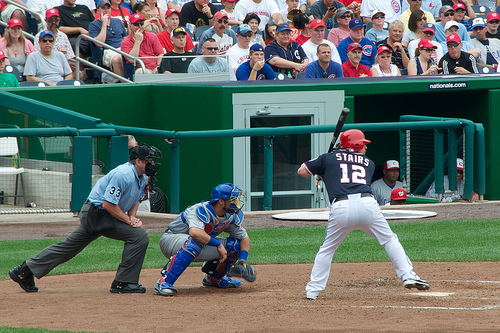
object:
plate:
[405, 291, 454, 296]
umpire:
[8, 143, 164, 294]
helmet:
[339, 129, 370, 153]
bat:
[314, 107, 351, 188]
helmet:
[208, 182, 243, 205]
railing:
[0, 91, 485, 217]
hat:
[128, 13, 146, 24]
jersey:
[302, 150, 376, 205]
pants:
[305, 191, 422, 297]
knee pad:
[160, 234, 204, 286]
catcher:
[154, 182, 257, 296]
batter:
[296, 128, 430, 300]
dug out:
[353, 88, 491, 206]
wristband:
[205, 235, 222, 249]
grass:
[0, 220, 499, 282]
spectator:
[304, 43, 345, 79]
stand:
[0, 0, 499, 90]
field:
[1, 200, 499, 333]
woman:
[406, 38, 443, 75]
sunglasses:
[418, 48, 436, 52]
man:
[437, 33, 480, 74]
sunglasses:
[446, 42, 461, 47]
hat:
[417, 38, 437, 49]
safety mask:
[144, 145, 163, 176]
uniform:
[153, 181, 257, 296]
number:
[339, 163, 367, 185]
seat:
[55, 79, 88, 86]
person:
[370, 159, 408, 205]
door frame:
[232, 89, 345, 212]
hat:
[445, 33, 461, 43]